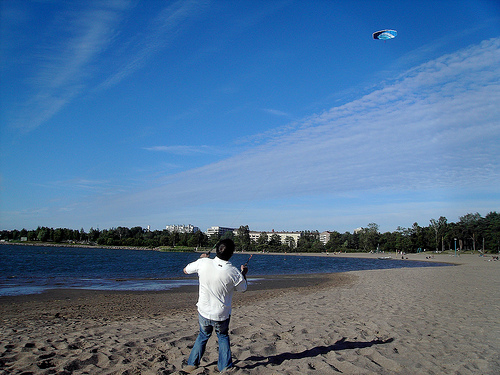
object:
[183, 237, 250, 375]
person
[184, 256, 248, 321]
shirt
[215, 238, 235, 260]
hair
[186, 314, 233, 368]
jeans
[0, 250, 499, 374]
sand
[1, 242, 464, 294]
water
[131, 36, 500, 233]
clouds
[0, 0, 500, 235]
sky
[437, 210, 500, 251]
trees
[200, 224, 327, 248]
building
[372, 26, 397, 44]
kite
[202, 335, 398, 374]
shadow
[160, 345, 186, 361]
footstep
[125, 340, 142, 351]
footstep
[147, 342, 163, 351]
footstep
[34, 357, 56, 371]
footstep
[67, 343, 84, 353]
footstep